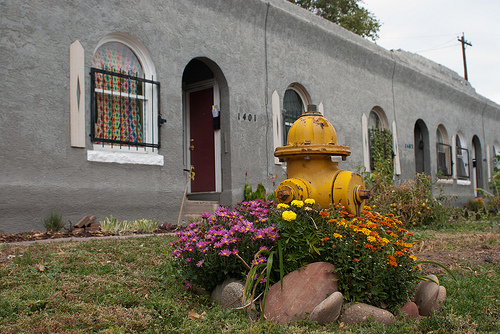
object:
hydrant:
[271, 102, 374, 221]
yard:
[1, 206, 499, 332]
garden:
[60, 194, 447, 332]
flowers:
[255, 254, 270, 265]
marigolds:
[280, 204, 299, 226]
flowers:
[398, 239, 414, 251]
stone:
[398, 46, 490, 88]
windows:
[276, 29, 324, 158]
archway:
[179, 53, 237, 228]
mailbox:
[209, 110, 225, 133]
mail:
[209, 102, 221, 121]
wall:
[183, 55, 231, 209]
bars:
[153, 64, 170, 154]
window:
[85, 30, 167, 169]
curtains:
[91, 40, 146, 148]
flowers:
[315, 234, 337, 245]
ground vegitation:
[0, 205, 499, 332]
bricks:
[72, 213, 88, 229]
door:
[187, 85, 219, 194]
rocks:
[208, 258, 257, 315]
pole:
[455, 32, 474, 85]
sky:
[292, 0, 500, 105]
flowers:
[166, 240, 179, 249]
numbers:
[236, 110, 242, 123]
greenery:
[367, 125, 397, 178]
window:
[362, 104, 397, 178]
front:
[1, 2, 497, 333]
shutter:
[465, 131, 494, 185]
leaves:
[366, 31, 384, 45]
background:
[288, 1, 499, 109]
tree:
[282, 0, 383, 45]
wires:
[462, 31, 469, 49]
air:
[357, 1, 499, 109]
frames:
[67, 32, 172, 180]